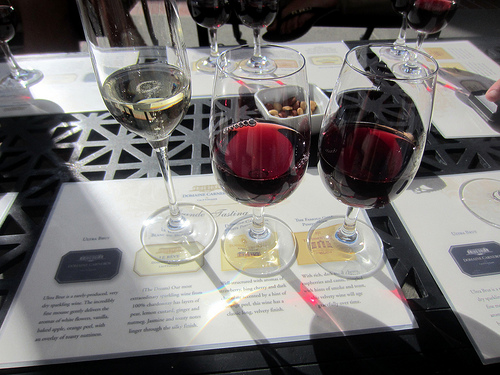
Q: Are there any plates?
A: Yes, there is a plate.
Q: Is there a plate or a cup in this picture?
A: Yes, there is a plate.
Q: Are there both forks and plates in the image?
A: No, there is a plate but no forks.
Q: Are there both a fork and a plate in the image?
A: No, there is a plate but no forks.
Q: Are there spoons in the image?
A: No, there are no spoons.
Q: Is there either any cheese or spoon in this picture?
A: No, there are no spoons or cheese.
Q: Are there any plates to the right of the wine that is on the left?
A: Yes, there is a plate to the right of the wine.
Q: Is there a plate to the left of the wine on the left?
A: No, the plate is to the right of the wine.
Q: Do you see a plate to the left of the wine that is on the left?
A: No, the plate is to the right of the wine.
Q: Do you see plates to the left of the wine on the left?
A: No, the plate is to the right of the wine.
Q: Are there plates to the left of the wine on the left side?
A: No, the plate is to the right of the wine.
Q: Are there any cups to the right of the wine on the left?
A: No, there is a plate to the right of the wine.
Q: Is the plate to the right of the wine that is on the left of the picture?
A: Yes, the plate is to the right of the wine.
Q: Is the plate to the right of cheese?
A: No, the plate is to the right of the wine.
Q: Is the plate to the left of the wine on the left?
A: No, the plate is to the right of the wine.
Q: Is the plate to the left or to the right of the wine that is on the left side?
A: The plate is to the right of the wine.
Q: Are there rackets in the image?
A: No, there are no rackets.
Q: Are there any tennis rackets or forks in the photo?
A: No, there are no tennis rackets or forks.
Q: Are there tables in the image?
A: Yes, there is a table.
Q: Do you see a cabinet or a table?
A: Yes, there is a table.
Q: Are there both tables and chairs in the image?
A: No, there is a table but no chairs.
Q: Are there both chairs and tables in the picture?
A: No, there is a table but no chairs.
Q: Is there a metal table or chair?
A: Yes, there is a metal table.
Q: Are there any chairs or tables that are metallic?
A: Yes, the table is metallic.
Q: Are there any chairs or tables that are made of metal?
A: Yes, the table is made of metal.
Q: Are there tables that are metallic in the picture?
A: Yes, there is a metal table.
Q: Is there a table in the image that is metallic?
A: Yes, there is a table that is metallic.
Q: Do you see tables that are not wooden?
A: Yes, there is a metallic table.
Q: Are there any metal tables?
A: Yes, there is a table that is made of metal.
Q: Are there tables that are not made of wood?
A: Yes, there is a table that is made of metal.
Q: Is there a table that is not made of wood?
A: Yes, there is a table that is made of metal.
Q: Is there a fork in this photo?
A: No, there are no forks.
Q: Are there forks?
A: No, there are no forks.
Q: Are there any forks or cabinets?
A: No, there are no forks or cabinets.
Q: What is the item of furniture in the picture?
A: The piece of furniture is a table.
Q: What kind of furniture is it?
A: The piece of furniture is a table.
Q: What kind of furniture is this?
A: This is a table.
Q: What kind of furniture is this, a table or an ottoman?
A: This is a table.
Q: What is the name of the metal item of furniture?
A: The piece of furniture is a table.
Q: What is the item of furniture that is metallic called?
A: The piece of furniture is a table.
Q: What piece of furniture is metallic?
A: The piece of furniture is a table.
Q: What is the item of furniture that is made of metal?
A: The piece of furniture is a table.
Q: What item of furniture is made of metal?
A: The piece of furniture is a table.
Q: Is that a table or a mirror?
A: That is a table.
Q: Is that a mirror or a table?
A: That is a table.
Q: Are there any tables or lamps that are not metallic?
A: No, there is a table but it is metallic.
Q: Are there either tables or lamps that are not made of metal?
A: No, there is a table but it is made of metal.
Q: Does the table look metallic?
A: Yes, the table is metallic.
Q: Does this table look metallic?
A: Yes, the table is metallic.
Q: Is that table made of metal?
A: Yes, the table is made of metal.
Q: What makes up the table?
A: The table is made of metal.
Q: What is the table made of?
A: The table is made of metal.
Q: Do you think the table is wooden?
A: No, the table is metallic.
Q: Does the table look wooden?
A: No, the table is metallic.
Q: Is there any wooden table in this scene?
A: No, there is a table but it is metallic.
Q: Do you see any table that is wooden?
A: No, there is a table but it is metallic.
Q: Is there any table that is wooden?
A: No, there is a table but it is metallic.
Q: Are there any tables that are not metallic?
A: No, there is a table but it is metallic.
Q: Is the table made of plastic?
A: No, the table is made of metal.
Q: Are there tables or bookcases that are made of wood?
A: No, there is a table but it is made of metal.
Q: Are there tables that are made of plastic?
A: No, there is a table but it is made of metal.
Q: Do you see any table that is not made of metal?
A: No, there is a table but it is made of metal.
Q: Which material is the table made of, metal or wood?
A: The table is made of metal.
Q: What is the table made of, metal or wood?
A: The table is made of metal.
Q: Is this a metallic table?
A: Yes, this is a metallic table.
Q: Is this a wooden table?
A: No, this is a metallic table.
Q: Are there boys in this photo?
A: No, there are no boys.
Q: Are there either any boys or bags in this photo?
A: No, there are no boys or bags.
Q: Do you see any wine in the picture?
A: Yes, there is wine.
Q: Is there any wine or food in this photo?
A: Yes, there is wine.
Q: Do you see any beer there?
A: No, there is no beer.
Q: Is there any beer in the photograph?
A: No, there is no beer.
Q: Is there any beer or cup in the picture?
A: No, there are no beer or cups.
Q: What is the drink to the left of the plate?
A: The drink is wine.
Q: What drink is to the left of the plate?
A: The drink is wine.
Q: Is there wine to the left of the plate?
A: Yes, there is wine to the left of the plate.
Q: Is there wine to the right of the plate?
A: No, the wine is to the left of the plate.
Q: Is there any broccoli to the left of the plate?
A: No, there is wine to the left of the plate.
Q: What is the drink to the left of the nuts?
A: The drink is wine.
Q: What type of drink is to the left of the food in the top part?
A: The drink is wine.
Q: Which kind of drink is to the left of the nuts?
A: The drink is wine.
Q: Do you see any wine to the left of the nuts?
A: Yes, there is wine to the left of the nuts.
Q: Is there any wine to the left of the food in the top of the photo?
A: Yes, there is wine to the left of the nuts.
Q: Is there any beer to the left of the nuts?
A: No, there is wine to the left of the nuts.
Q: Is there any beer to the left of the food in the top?
A: No, there is wine to the left of the nuts.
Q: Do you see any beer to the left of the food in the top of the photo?
A: No, there is wine to the left of the nuts.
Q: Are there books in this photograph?
A: No, there are no books.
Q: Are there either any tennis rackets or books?
A: No, there are no books or tennis rackets.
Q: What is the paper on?
A: The paper is on the table.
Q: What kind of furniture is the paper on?
A: The paper is on the table.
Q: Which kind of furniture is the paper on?
A: The paper is on the table.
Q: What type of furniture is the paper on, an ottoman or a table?
A: The paper is on a table.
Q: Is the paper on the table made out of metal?
A: Yes, the paper is on the table.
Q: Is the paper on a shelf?
A: No, the paper is on the table.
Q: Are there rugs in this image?
A: No, there are no rugs.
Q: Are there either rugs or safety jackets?
A: No, there are no rugs or safety jackets.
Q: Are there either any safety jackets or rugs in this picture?
A: No, there are no rugs or safety jackets.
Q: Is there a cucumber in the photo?
A: No, there are no cucumbers.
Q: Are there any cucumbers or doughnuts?
A: No, there are no cucumbers or doughnuts.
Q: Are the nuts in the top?
A: Yes, the nuts are in the top of the image.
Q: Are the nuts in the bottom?
A: No, the nuts are in the top of the image.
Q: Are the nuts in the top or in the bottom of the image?
A: The nuts are in the top of the image.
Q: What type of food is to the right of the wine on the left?
A: The food is nuts.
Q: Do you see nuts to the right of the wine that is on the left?
A: Yes, there are nuts to the right of the wine.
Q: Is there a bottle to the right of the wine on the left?
A: No, there are nuts to the right of the wine.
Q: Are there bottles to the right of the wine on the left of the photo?
A: No, there are nuts to the right of the wine.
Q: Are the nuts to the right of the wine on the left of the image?
A: Yes, the nuts are to the right of the wine.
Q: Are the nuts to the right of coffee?
A: No, the nuts are to the right of the wine.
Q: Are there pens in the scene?
A: No, there are no pens.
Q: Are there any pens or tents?
A: No, there are no pens or tents.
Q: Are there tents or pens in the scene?
A: No, there are no pens or tents.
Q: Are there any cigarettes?
A: No, there are no cigarettes.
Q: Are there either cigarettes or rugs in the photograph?
A: No, there are no cigarettes or rugs.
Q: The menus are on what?
A: The menus are on the table.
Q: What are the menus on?
A: The menus are on the table.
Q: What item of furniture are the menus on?
A: The menus are on the table.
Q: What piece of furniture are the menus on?
A: The menus are on the table.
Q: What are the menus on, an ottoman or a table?
A: The menus are on a table.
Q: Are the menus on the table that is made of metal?
A: Yes, the menus are on the table.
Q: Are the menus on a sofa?
A: No, the menus are on the table.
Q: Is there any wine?
A: Yes, there is wine.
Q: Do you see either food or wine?
A: Yes, there is wine.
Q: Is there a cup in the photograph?
A: No, there are no cups.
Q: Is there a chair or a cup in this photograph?
A: No, there are no cups or chairs.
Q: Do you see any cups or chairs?
A: No, there are no cups or chairs.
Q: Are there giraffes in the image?
A: No, there are no giraffes.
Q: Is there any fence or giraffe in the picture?
A: No, there are no giraffes or fences.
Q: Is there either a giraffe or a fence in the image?
A: No, there are no giraffes or fences.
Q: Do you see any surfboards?
A: No, there are no surfboards.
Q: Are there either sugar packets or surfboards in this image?
A: No, there are no surfboards or sugar packets.